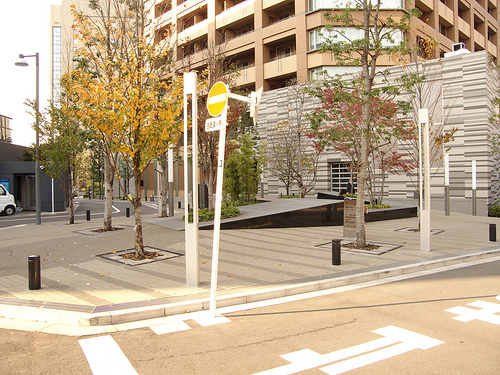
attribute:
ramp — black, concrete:
[180, 190, 350, 235]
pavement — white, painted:
[163, 278, 494, 371]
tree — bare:
[257, 80, 331, 207]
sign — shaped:
[205, 85, 230, 122]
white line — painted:
[444, 292, 499, 328]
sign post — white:
[204, 110, 231, 310]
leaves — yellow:
[108, 80, 121, 95]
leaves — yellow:
[143, 69, 163, 91]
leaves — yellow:
[68, 81, 83, 106]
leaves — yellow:
[107, 116, 125, 128]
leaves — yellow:
[157, 123, 170, 142]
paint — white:
[220, 317, 446, 372]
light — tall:
[16, 51, 46, 223]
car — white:
[2, 178, 16, 225]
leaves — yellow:
[33, 0, 185, 180]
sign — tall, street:
[185, 81, 260, 306]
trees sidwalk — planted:
[59, 17, 166, 264]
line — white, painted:
[145, 308, 229, 333]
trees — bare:
[282, 136, 330, 196]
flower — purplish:
[308, 137, 325, 153]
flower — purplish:
[378, 150, 410, 172]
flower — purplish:
[323, 86, 336, 101]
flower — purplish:
[383, 100, 396, 110]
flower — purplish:
[334, 122, 351, 132]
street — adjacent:
[229, 225, 307, 287]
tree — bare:
[384, 48, 465, 193]